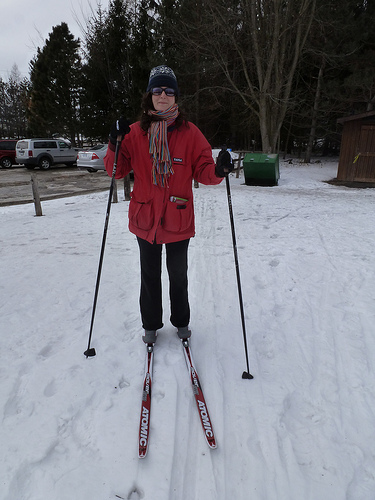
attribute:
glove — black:
[211, 147, 234, 178]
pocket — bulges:
[128, 196, 158, 235]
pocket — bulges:
[160, 199, 195, 232]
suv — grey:
[14, 131, 77, 179]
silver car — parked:
[76, 140, 109, 172]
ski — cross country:
[180, 338, 216, 449]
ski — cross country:
[136, 329, 155, 457]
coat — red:
[100, 118, 223, 245]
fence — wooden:
[0, 159, 117, 217]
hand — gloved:
[213, 142, 234, 176]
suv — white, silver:
[15, 136, 81, 169]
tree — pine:
[21, 25, 85, 146]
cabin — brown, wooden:
[332, 85, 371, 182]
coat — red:
[92, 113, 228, 244]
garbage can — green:
[240, 146, 299, 201]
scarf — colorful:
[130, 103, 188, 190]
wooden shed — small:
[327, 109, 373, 199]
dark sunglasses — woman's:
[152, 86, 178, 97]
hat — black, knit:
[143, 62, 179, 96]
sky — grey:
[3, 0, 148, 94]